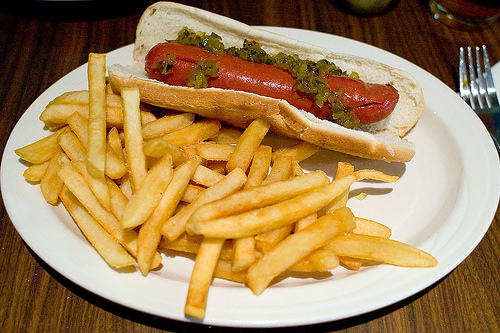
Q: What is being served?
A: A hot dog and fries.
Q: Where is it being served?
A: On a table.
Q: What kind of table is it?
A: Wood.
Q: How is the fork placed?
A: To the right of the plate.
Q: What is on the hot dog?
A: Relish.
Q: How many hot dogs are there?
A: One.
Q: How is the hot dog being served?
A: On a bun.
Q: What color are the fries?
A: Golden brown.